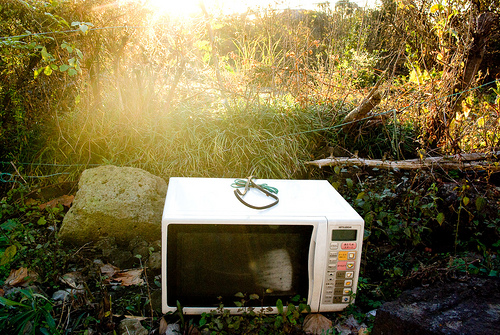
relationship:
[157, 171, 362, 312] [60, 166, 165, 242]
microwave near rock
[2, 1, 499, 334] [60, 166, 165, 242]
trees behind rock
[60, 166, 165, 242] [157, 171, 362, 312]
rock with microwave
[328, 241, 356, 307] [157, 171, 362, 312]
buttons of microwave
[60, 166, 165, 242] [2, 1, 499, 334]
rock near trees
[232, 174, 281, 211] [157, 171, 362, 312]
cord on top of microwave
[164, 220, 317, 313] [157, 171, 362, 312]
window of microwave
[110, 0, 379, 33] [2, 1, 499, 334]
sun near trees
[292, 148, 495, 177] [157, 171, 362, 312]
tree behind microwave